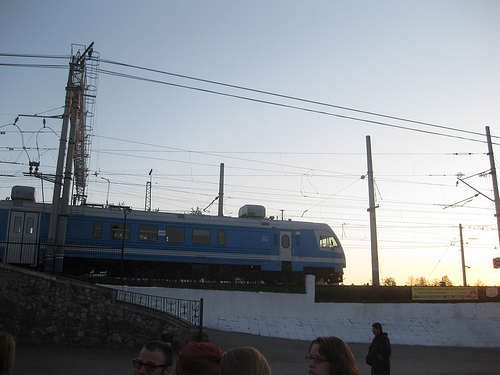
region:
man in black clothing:
[365, 317, 400, 374]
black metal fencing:
[125, 287, 215, 332]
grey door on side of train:
[2, 203, 48, 267]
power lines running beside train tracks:
[142, 57, 402, 138]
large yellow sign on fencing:
[404, 280, 483, 309]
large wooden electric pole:
[344, 124, 394, 289]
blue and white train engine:
[2, 189, 361, 275]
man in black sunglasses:
[122, 353, 179, 373]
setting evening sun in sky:
[375, 173, 498, 295]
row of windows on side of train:
[82, 216, 239, 258]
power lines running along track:
[144, 54, 374, 131]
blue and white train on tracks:
[2, 192, 357, 299]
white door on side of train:
[6, 207, 43, 268]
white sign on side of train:
[152, 225, 167, 244]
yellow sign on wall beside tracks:
[396, 280, 478, 305]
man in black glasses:
[127, 344, 167, 374]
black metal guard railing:
[114, 280, 221, 332]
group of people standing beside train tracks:
[84, 317, 421, 374]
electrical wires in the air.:
[164, 64, 215, 94]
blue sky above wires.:
[141, 14, 228, 48]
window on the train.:
[163, 228, 185, 240]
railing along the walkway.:
[145, 297, 206, 312]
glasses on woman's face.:
[303, 355, 328, 362]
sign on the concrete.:
[410, 289, 487, 301]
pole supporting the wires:
[362, 155, 383, 280]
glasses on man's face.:
[123, 360, 160, 371]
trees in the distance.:
[400, 275, 452, 283]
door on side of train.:
[279, 232, 294, 269]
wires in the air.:
[187, 67, 257, 106]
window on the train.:
[192, 230, 209, 240]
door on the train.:
[277, 231, 292, 261]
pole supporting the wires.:
[367, 187, 382, 287]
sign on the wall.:
[410, 289, 482, 307]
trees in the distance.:
[386, 273, 440, 285]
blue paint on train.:
[236, 234, 260, 246]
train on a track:
[6, 173, 379, 315]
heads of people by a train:
[133, 329, 357, 372]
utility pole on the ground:
[357, 123, 399, 283]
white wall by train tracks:
[207, 288, 498, 360]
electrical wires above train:
[156, 62, 476, 159]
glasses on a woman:
[303, 350, 333, 369]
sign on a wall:
[406, 278, 488, 305]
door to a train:
[269, 229, 304, 266]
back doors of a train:
[2, 203, 49, 278]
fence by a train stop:
[108, 278, 218, 333]